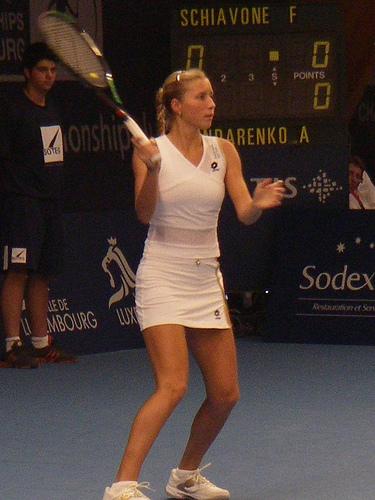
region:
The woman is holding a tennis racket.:
[35, 8, 288, 499]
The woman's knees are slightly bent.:
[93, 60, 296, 498]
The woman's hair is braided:
[107, 61, 288, 244]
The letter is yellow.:
[176, 6, 190, 30]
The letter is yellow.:
[187, 5, 200, 32]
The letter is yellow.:
[197, 3, 212, 29]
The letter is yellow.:
[214, 4, 230, 29]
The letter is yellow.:
[225, 5, 243, 29]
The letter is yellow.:
[248, 4, 263, 31]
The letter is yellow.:
[259, 1, 273, 28]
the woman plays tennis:
[30, 9, 297, 498]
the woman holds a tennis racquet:
[31, 9, 163, 167]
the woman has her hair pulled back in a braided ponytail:
[155, 83, 166, 134]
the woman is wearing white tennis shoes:
[100, 467, 242, 499]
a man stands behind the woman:
[1, 52, 74, 369]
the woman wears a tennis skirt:
[132, 244, 240, 335]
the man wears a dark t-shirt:
[8, 90, 71, 201]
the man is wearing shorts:
[7, 194, 70, 274]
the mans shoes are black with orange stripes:
[0, 335, 81, 374]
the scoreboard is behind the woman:
[174, 6, 337, 123]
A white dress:
[162, 133, 223, 307]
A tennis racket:
[75, 36, 139, 138]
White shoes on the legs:
[106, 465, 229, 498]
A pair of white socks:
[95, 469, 206, 488]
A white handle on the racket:
[121, 111, 152, 154]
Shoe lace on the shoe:
[185, 456, 208, 484]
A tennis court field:
[285, 363, 341, 448]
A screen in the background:
[239, 34, 338, 124]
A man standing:
[6, 52, 75, 234]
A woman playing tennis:
[115, 59, 257, 460]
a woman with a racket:
[24, 4, 288, 498]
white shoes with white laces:
[164, 459, 229, 498]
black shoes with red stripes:
[0, 331, 90, 375]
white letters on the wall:
[280, 245, 372, 329]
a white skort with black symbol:
[106, 236, 251, 345]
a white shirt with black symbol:
[128, 127, 252, 268]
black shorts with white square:
[2, 201, 78, 283]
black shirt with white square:
[10, 100, 83, 207]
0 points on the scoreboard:
[298, 40, 349, 138]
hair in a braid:
[137, 62, 228, 171]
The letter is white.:
[292, 258, 315, 299]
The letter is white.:
[313, 267, 332, 294]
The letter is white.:
[329, 259, 348, 293]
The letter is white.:
[344, 268, 364, 299]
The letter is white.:
[360, 270, 374, 298]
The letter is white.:
[85, 306, 99, 332]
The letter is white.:
[70, 309, 85, 333]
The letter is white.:
[52, 311, 67, 333]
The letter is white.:
[42, 311, 60, 335]